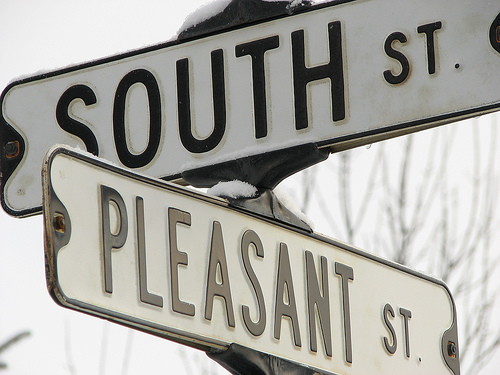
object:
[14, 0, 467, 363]
street sign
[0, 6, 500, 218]
black/white sign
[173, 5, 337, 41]
pole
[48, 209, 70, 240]
screw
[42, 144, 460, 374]
sign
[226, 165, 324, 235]
pole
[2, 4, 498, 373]
wall